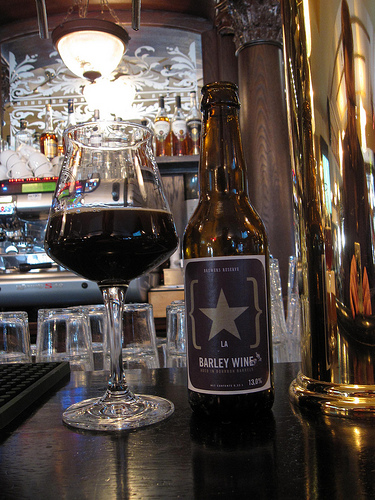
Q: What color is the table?
A: The table is black.